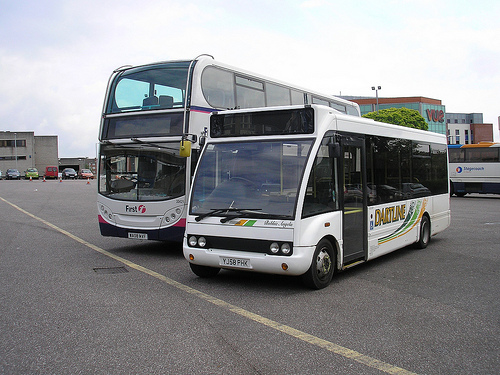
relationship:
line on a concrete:
[179, 290, 356, 341] [216, 294, 317, 372]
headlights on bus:
[188, 231, 305, 258] [183, 104, 451, 290]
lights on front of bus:
[96, 201, 181, 226] [90, 58, 367, 245]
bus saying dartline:
[183, 104, 451, 290] [373, 203, 408, 229]